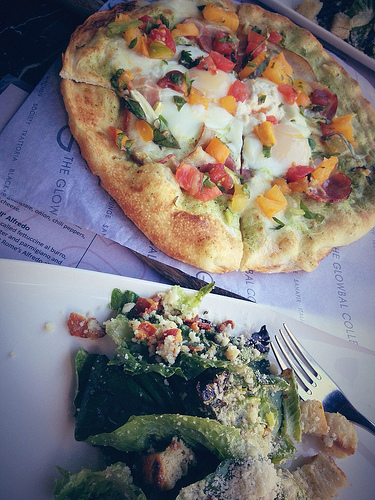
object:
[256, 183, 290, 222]
pepper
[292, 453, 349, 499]
crouton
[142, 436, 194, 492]
crouton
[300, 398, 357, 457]
crouton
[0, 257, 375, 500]
plate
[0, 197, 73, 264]
restaurant menu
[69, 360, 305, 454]
leaf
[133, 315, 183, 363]
cheese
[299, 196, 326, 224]
scallions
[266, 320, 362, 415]
motorcycle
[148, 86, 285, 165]
cheese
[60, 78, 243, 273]
crust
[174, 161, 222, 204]
tomato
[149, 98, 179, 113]
wall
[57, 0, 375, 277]
food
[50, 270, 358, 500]
food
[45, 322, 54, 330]
crumb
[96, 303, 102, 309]
crumb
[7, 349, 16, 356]
crumb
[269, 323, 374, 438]
fork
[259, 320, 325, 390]
top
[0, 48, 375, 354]
paper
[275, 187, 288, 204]
bit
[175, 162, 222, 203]
part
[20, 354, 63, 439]
part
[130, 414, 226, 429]
edge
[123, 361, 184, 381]
edge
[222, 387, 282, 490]
cheese